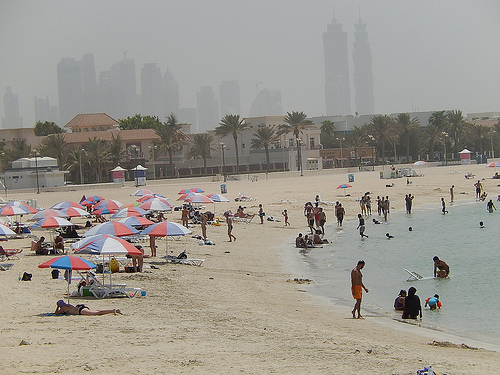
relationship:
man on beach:
[349, 260, 369, 319] [21, 164, 483, 374]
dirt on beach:
[5, 167, 499, 374] [0, 160, 500, 374]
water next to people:
[309, 196, 499, 343] [293, 190, 413, 252]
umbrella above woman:
[35, 252, 100, 296] [53, 300, 123, 316]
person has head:
[437, 197, 496, 247] [476, 220, 484, 230]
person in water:
[437, 197, 496, 247] [369, 244, 429, 274]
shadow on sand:
[37, 310, 61, 322] [175, 262, 253, 347]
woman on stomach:
[53, 300, 123, 316] [61, 308, 76, 318]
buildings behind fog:
[15, 12, 433, 118] [0, 1, 500, 133]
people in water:
[327, 184, 458, 336] [303, 190, 498, 336]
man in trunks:
[347, 260, 369, 315] [349, 283, 365, 298]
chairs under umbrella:
[67, 266, 153, 323] [35, 252, 100, 296]